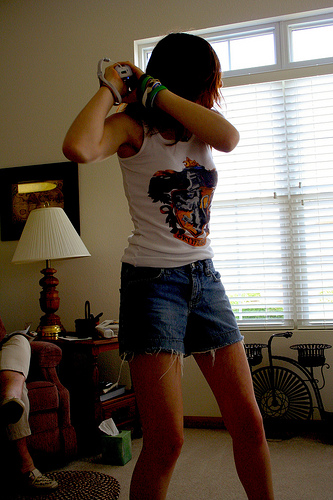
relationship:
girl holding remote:
[123, 34, 267, 500] [105, 58, 135, 81]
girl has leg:
[123, 34, 267, 500] [128, 311, 185, 499]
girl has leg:
[123, 34, 267, 500] [197, 325, 275, 500]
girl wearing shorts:
[123, 34, 267, 500] [113, 258, 245, 353]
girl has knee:
[123, 34, 267, 500] [164, 426, 185, 460]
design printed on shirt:
[154, 160, 212, 242] [118, 108, 220, 266]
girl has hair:
[123, 34, 267, 500] [147, 34, 225, 100]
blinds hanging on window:
[237, 96, 332, 323] [211, 19, 332, 332]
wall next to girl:
[10, 22, 79, 108] [123, 34, 267, 500]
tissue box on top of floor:
[102, 418, 132, 465] [105, 462, 332, 500]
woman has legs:
[1, 307, 60, 493] [1, 328, 59, 494]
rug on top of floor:
[26, 471, 118, 500] [105, 462, 332, 500]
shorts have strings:
[113, 258, 245, 353] [120, 353, 187, 374]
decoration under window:
[249, 337, 332, 439] [211, 19, 332, 332]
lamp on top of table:
[13, 204, 91, 339] [60, 333, 128, 424]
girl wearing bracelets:
[123, 34, 267, 500] [135, 75, 165, 106]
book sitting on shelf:
[101, 384, 125, 400] [101, 392, 142, 414]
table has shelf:
[60, 333, 128, 424] [101, 392, 142, 414]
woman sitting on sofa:
[1, 307, 60, 493] [30, 351, 75, 464]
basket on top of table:
[77, 301, 97, 335] [60, 333, 128, 424]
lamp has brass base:
[13, 204, 91, 339] [36, 322, 70, 338]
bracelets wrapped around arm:
[135, 75, 165, 106] [149, 90, 236, 151]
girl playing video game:
[123, 34, 267, 500] [97, 64, 137, 102]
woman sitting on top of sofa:
[1, 307, 60, 493] [30, 351, 75, 464]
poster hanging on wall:
[1, 165, 77, 212] [10, 22, 79, 108]